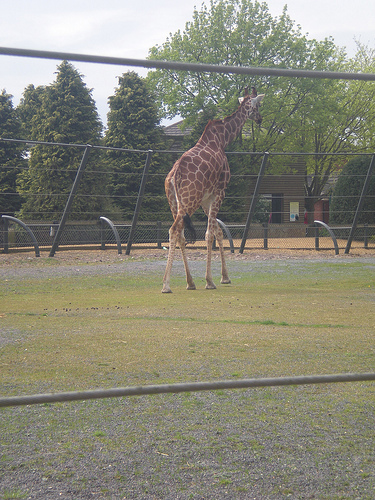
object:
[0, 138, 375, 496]
enclosure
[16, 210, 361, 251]
structure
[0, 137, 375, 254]
fence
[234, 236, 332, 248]
ground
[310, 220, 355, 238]
wall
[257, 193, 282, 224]
window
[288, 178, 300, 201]
plaque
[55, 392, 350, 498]
ground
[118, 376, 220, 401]
post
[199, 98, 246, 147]
neck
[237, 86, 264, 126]
head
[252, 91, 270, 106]
ear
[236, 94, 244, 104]
ear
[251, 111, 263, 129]
mouth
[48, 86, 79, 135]
leaves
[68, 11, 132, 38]
sky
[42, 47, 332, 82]
pole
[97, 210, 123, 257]
pole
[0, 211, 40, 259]
pole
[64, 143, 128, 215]
pole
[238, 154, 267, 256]
pole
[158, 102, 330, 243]
building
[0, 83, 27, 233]
trees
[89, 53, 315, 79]
bar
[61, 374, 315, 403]
bar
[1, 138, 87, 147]
posts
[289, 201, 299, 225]
sign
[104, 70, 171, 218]
trees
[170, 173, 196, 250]
tail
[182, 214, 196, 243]
hair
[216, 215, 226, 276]
legs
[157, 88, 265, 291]
giraffe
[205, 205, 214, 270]
leg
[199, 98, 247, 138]
mane